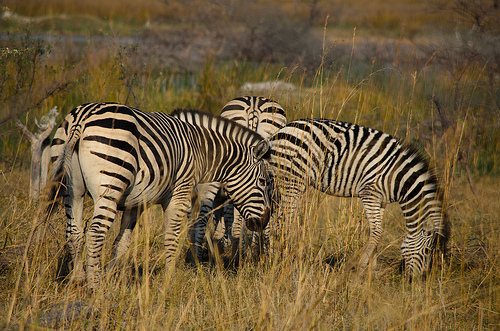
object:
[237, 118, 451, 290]
zebras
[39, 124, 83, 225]
tail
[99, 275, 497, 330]
grass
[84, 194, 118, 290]
legs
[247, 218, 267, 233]
mouth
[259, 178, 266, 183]
eye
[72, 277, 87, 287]
hoof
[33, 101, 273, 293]
zebra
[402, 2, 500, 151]
tree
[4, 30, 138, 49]
river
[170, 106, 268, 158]
mane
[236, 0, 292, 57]
tree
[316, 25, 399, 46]
dirt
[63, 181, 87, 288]
left rear leg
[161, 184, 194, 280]
right front leg